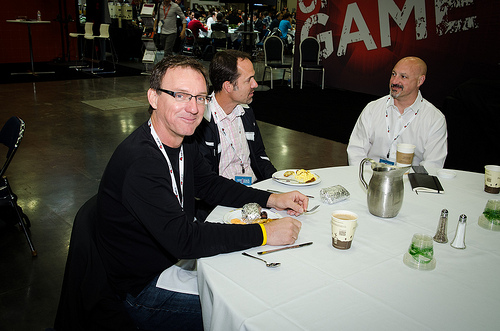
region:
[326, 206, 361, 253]
white and brown cup of coffee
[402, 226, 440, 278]
upside down plastic cups with a green design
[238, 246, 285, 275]
shiny metal spoon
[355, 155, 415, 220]
a silver pitcher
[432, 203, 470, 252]
salt and pepper shakers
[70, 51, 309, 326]
two men sitting at a table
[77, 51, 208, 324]
a smiling man with glasses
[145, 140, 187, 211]
white neck lanyard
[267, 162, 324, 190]
a plate of some yellow colored food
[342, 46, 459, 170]
a bald man with a moustache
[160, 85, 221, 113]
Man with glasses on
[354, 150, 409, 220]
Silver water picture on table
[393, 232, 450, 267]
Upside down plastic cup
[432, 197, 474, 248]
Salt and pepper shakers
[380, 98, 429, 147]
Lanyard around mans neck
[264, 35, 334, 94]
Two black and silver chairs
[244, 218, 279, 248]
Yellow plastic bracelet on wrist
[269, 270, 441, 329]
Creased white tablecloth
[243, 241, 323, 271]
Silver flatware on table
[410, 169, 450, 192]
Man's black notebook on table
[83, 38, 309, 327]
Men sitting at a table.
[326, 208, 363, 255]
Cup of coffee sitting on table.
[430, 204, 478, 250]
Salt and pepper shakers sitting on table.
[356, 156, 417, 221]
Pitcher sitting on table.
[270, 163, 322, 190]
Plate of food sitting on table in front of man.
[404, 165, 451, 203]
Black book laying on table.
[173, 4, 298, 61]
People sitting at tables in background.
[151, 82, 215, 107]
Man wearing eyeglasses over eyes.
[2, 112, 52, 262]
Back portion of chair at table.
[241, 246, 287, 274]
Spoon laying on table.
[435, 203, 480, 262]
salt and pepper on the table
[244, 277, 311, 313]
the tablecloth is white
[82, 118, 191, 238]
the shirt is black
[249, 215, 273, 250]
the bracelet is yellow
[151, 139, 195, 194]
the lanyard is white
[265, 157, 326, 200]
the food on the plate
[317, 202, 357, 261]
the cup on the table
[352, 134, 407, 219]
the pitcher is silver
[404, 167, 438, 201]
the notebook is black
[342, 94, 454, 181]
the shirt is white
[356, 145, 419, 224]
a metal water pitcher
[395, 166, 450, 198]
a notebook and a pen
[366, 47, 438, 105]
a man with a mustache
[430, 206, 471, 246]
salt and pepper shaker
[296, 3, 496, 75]
a red banner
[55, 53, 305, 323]
a man with meeting credentials around his neck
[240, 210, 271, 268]
a yellow wrist band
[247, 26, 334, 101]
two chairs in the background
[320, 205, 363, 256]
cup of coffee with cream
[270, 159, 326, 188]
some eggs and other breakfast food